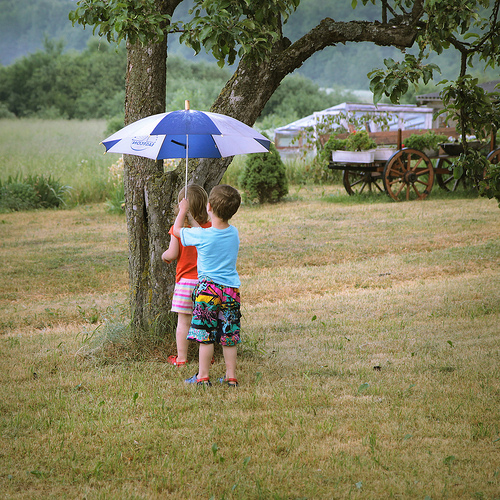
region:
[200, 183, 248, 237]
head of a person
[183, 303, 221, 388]
leg of a person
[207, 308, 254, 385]
leg of a person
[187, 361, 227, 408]
feet of a person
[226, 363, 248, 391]
feet of a person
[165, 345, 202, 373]
feet of a person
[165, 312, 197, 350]
leg of a person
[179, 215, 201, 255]
arm of a person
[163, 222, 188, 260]
arm of a person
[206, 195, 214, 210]
ear of a person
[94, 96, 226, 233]
a white and blue umbrella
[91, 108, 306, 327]
kids underneath an umbrella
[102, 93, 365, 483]
kids standing on grass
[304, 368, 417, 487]
a field of grass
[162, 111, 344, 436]
two children on the grass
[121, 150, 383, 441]
children on the grass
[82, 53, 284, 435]
a boy holding an umbrella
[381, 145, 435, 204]
wheel of the cart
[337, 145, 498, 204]
wheels of the cart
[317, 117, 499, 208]
cart on the ground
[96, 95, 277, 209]
an umbrella the boy is holding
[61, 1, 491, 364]
a tree in the field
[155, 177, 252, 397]
boy and girl next to the tree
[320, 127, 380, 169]
plants on the pot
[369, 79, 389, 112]
a leaf on the tree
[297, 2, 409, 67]
a branch on the tree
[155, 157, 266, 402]
Two young children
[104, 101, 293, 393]
The boy is holding an umbrella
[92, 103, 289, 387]
The umbrella is over the girl's head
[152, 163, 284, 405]
The kids are next to a tree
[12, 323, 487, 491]
The ground is covered in grass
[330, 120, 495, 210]
A cart with pants on it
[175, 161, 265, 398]
The boy is using both hands to hold the umbrella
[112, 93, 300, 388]
The boy is behind the girl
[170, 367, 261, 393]
The boy is wearing sandles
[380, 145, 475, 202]
The wheels are round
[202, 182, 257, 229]
head of a person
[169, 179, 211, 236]
head of a person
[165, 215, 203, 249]
arm of a person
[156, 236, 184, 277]
arm of a person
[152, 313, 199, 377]
leg of a person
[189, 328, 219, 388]
leg of a person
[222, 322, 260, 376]
leg of a person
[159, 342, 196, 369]
feet of a person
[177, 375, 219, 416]
feet of a person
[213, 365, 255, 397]
feet of a person